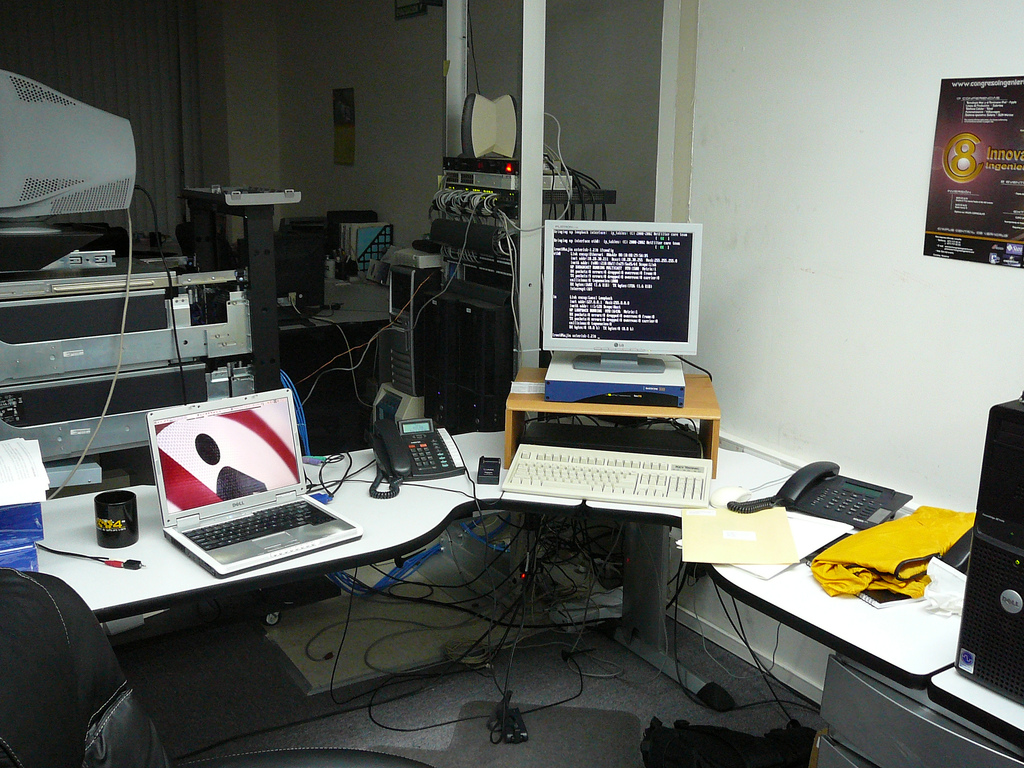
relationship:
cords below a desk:
[442, 564, 609, 720] [163, 430, 814, 593]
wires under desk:
[306, 505, 626, 687] [2, 386, 1022, 736]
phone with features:
[726, 461, 913, 531] [812, 473, 901, 525]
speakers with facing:
[444, 73, 561, 184] [464, 92, 484, 170]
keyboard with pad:
[494, 440, 745, 521] [656, 470, 723, 523]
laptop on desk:
[138, 377, 355, 585] [2, 386, 1022, 736]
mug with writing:
[77, 488, 145, 549] [90, 516, 132, 549]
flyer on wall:
[907, 69, 1022, 273] [684, 4, 1022, 523]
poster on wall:
[936, 80, 1021, 206] [703, 23, 984, 466]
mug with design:
[95, 492, 139, 550] [113, 404, 395, 517]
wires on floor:
[413, 499, 684, 674] [338, 589, 628, 715]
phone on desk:
[754, 415, 979, 612] [268, 443, 919, 677]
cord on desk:
[18, 525, 193, 623] [70, 402, 475, 567]